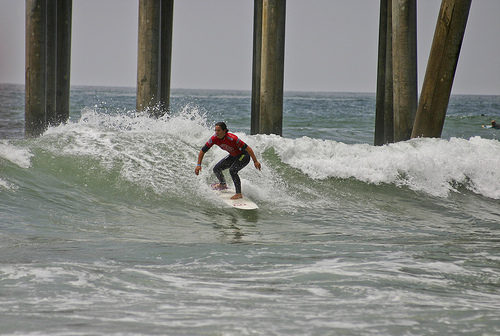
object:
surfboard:
[210, 182, 259, 210]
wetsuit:
[201, 132, 251, 193]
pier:
[23, 0, 471, 147]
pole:
[23, 0, 49, 144]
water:
[0, 84, 500, 336]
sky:
[0, 0, 500, 96]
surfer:
[482, 120, 500, 131]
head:
[491, 120, 496, 126]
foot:
[230, 193, 243, 199]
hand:
[254, 161, 261, 171]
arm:
[194, 133, 216, 175]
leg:
[229, 152, 251, 199]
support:
[134, 0, 164, 119]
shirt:
[201, 132, 248, 156]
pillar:
[250, 0, 287, 138]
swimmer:
[481, 114, 484, 116]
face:
[215, 125, 226, 139]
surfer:
[194, 122, 261, 200]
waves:
[0, 100, 500, 214]